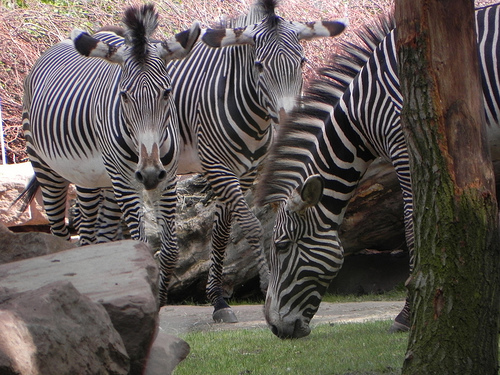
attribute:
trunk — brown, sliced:
[415, 46, 488, 184]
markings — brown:
[274, 43, 288, 73]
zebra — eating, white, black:
[33, 5, 174, 232]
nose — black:
[132, 155, 168, 190]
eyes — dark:
[120, 87, 173, 100]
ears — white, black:
[205, 21, 344, 45]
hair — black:
[228, 73, 234, 99]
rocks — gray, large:
[3, 233, 161, 374]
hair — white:
[224, 101, 230, 116]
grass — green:
[255, 350, 357, 374]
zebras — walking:
[18, 7, 442, 362]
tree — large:
[396, 22, 470, 104]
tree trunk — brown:
[406, 13, 469, 43]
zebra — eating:
[263, 125, 351, 361]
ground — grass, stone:
[332, 303, 383, 319]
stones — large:
[31, 271, 148, 327]